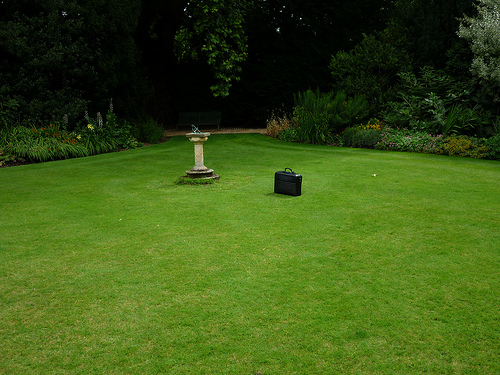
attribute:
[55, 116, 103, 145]
flowers — white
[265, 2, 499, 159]
plants — landscaped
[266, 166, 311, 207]
briefcase — black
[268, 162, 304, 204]
suitcase — black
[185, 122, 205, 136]
dial — green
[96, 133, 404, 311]
back yard — suspicious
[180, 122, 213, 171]
feeder — bird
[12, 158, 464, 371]
lawn — green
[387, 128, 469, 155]
leaves — yellow, green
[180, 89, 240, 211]
birdbath — white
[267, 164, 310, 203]
briefcase — black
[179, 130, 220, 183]
decoration — yard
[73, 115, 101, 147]
flower bulbs — white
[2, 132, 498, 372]
grass — small, patchy, smooth, green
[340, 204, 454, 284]
turf — fresh, cut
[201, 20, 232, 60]
leaves — green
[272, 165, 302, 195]
object — beige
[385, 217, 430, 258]
patch — green, grassy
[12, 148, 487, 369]
turf — freshly cut